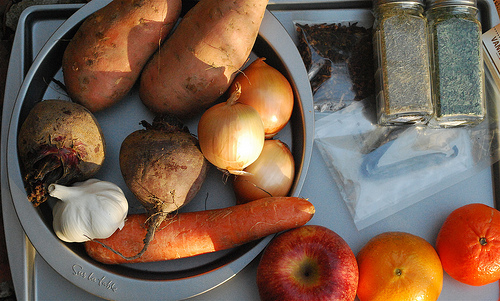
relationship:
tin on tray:
[259, 15, 310, 115] [4, 2, 68, 80]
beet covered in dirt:
[114, 110, 216, 258] [155, 158, 172, 170]